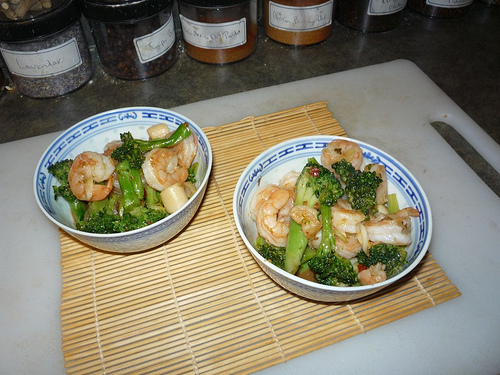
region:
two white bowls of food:
[33, 104, 433, 303]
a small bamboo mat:
[43, 98, 460, 373]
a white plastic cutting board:
[0, 57, 499, 374]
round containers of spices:
[1, 0, 470, 100]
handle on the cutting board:
[425, 109, 497, 199]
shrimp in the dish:
[69, 149, 115, 199]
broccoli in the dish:
[110, 120, 190, 166]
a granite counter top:
[1, 0, 497, 194]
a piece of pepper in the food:
[308, 165, 319, 178]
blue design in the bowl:
[33, 107, 208, 218]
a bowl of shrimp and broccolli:
[233, 134, 433, 309]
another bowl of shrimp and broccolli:
[32, 105, 215, 255]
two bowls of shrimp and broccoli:
[33, 102, 436, 302]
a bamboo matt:
[65, 98, 464, 374]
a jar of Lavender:
[0, 1, 101, 98]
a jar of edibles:
[82, 1, 181, 79]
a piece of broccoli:
[117, 133, 145, 209]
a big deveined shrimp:
[257, 185, 291, 245]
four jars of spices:
[2, 1, 339, 91]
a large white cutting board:
[3, 63, 495, 372]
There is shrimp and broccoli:
[249, 163, 429, 291]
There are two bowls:
[22, 133, 463, 324]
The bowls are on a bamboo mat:
[21, 131, 443, 320]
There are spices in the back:
[4, 19, 388, 68]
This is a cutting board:
[348, 72, 496, 228]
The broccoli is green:
[308, 174, 385, 286]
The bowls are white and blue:
[241, 148, 339, 246]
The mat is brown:
[83, 288, 200, 372]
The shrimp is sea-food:
[38, 136, 181, 232]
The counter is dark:
[83, 93, 174, 109]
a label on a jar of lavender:
[1, 46, 85, 75]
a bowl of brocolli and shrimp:
[38, 104, 205, 239]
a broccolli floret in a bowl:
[335, 155, 382, 212]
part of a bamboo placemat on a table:
[57, 267, 292, 368]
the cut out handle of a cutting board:
[413, 102, 499, 189]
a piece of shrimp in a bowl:
[256, 185, 291, 234]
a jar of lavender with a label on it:
[3, 10, 93, 97]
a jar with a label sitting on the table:
[91, 1, 186, 80]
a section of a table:
[175, 67, 252, 89]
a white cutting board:
[336, 75, 437, 122]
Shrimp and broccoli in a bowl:
[62, 147, 150, 212]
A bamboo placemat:
[73, 269, 289, 358]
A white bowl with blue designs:
[40, 117, 222, 237]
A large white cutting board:
[298, 55, 458, 162]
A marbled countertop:
[337, 33, 493, 87]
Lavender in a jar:
[8, 7, 106, 100]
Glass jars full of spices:
[82, 8, 432, 68]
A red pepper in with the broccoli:
[354, 257, 373, 275]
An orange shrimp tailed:
[89, 169, 121, 205]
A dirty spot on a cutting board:
[432, 108, 455, 124]